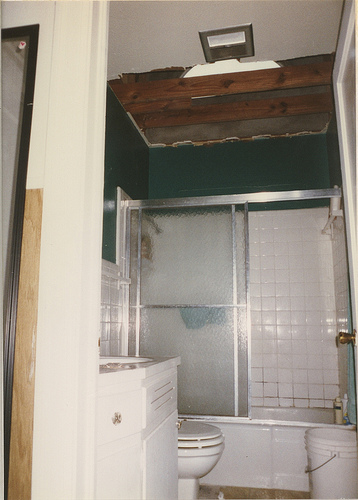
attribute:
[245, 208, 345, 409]
tiles — white, moldy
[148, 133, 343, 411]
wall — tiled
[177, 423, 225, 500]
toilet — white, here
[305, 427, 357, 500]
bucket — white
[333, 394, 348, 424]
products — here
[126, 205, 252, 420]
doors — glass, translucent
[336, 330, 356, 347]
doorknob — gold, brass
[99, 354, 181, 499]
sink — white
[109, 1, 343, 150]
ceiling — broken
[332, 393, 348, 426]
shampoo — here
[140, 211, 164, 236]
showerhead — brass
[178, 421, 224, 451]
seat — closed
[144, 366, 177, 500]
cabinets — closed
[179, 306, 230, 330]
towel — blue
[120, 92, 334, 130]
wood — here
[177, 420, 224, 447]
toilet seat — here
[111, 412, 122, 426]
knobs — glass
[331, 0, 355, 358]
frame — wooden